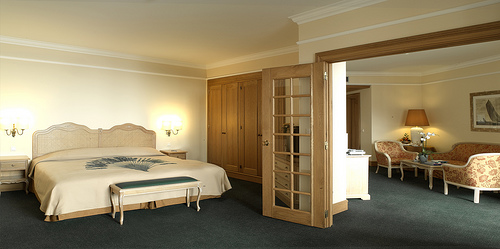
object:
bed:
[27, 121, 232, 221]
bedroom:
[0, 0, 314, 248]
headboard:
[31, 122, 156, 154]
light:
[3, 110, 31, 141]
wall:
[0, 41, 207, 163]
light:
[162, 114, 182, 137]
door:
[261, 61, 328, 229]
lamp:
[402, 109, 429, 144]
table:
[404, 144, 437, 155]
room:
[0, 0, 500, 248]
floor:
[348, 197, 497, 247]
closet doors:
[205, 70, 285, 183]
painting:
[469, 89, 499, 132]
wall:
[424, 62, 499, 151]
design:
[84, 155, 177, 171]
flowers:
[417, 131, 435, 160]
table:
[397, 157, 446, 190]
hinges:
[321, 209, 330, 218]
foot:
[361, 192, 373, 201]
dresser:
[345, 153, 372, 200]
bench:
[106, 176, 204, 224]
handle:
[261, 138, 269, 146]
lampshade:
[404, 107, 431, 125]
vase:
[417, 150, 428, 165]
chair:
[373, 139, 420, 178]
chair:
[440, 151, 499, 203]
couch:
[426, 141, 499, 179]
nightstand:
[1, 155, 33, 195]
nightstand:
[159, 149, 186, 161]